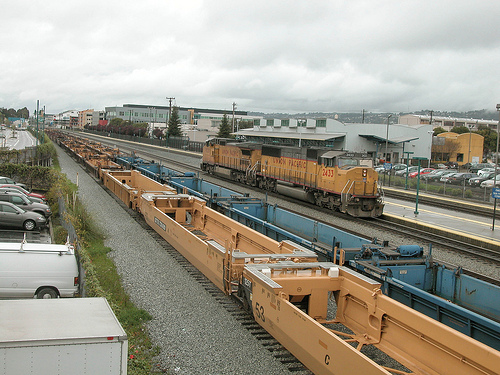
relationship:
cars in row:
[1, 172, 55, 239] [0, 168, 130, 372]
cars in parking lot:
[1, 172, 55, 239] [0, 168, 130, 372]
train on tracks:
[200, 134, 401, 224] [391, 212, 499, 267]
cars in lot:
[1, 172, 55, 239] [0, 168, 130, 372]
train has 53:
[240, 272, 492, 374] [249, 299, 273, 329]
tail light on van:
[74, 276, 83, 288] [3, 232, 86, 299]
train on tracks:
[240, 272, 492, 374] [101, 132, 500, 374]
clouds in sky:
[218, 19, 342, 76] [10, 3, 498, 127]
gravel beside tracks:
[106, 224, 145, 261] [101, 132, 500, 374]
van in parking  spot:
[3, 232, 86, 299] [0, 225, 51, 240]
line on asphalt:
[456, 214, 474, 221] [388, 192, 498, 240]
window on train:
[338, 156, 357, 168] [200, 134, 401, 224]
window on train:
[362, 159, 374, 167] [200, 134, 401, 224]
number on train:
[321, 168, 336, 178] [200, 134, 401, 224]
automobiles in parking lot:
[1, 179, 119, 369] [0, 168, 130, 372]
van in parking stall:
[3, 232, 86, 299] [0, 225, 51, 240]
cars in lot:
[392, 160, 500, 192] [379, 153, 498, 197]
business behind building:
[434, 133, 489, 166] [254, 113, 444, 161]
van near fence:
[3, 232, 86, 299] [53, 188, 88, 246]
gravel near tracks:
[106, 224, 145, 261] [101, 132, 500, 374]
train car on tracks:
[75, 145, 179, 194] [101, 132, 500, 374]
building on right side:
[254, 113, 444, 161] [78, 84, 499, 186]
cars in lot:
[392, 160, 500, 192] [381, 143, 500, 214]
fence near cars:
[53, 188, 88, 246] [1, 172, 55, 239]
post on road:
[414, 155, 428, 216] [388, 192, 498, 240]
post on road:
[397, 149, 415, 194] [388, 192, 498, 240]